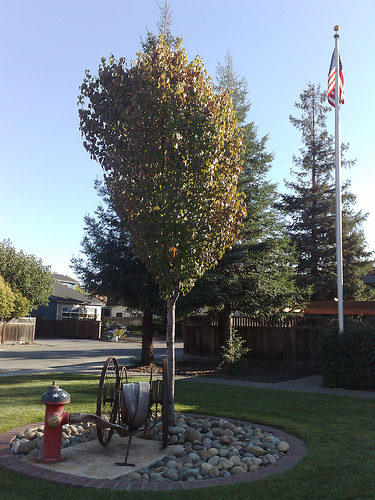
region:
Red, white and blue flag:
[322, 40, 349, 113]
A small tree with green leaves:
[78, 31, 249, 453]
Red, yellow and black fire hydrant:
[37, 377, 74, 464]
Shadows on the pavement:
[0, 340, 185, 378]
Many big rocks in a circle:
[1, 403, 308, 495]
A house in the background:
[31, 271, 103, 338]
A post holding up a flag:
[326, 85, 352, 333]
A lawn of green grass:
[2, 367, 370, 495]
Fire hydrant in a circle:
[4, 378, 304, 491]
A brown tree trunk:
[134, 314, 159, 364]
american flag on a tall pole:
[326, 21, 345, 338]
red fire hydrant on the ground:
[35, 379, 70, 463]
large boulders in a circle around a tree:
[0, 399, 308, 490]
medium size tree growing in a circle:
[78, 51, 249, 437]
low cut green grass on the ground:
[0, 372, 372, 496]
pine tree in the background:
[277, 84, 370, 297]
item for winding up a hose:
[93, 354, 170, 470]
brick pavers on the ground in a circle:
[82, 469, 259, 492]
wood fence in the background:
[181, 311, 326, 363]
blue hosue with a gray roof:
[34, 270, 105, 318]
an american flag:
[324, 43, 346, 107]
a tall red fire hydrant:
[38, 380, 71, 463]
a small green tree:
[219, 328, 251, 373]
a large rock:
[276, 439, 291, 453]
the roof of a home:
[44, 275, 102, 305]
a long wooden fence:
[184, 317, 322, 362]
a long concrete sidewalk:
[135, 367, 369, 399]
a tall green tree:
[67, 76, 304, 364]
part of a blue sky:
[1, 0, 109, 40]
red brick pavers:
[127, 478, 181, 493]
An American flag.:
[326, 49, 346, 110]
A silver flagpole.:
[331, 24, 346, 336]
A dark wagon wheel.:
[92, 359, 120, 449]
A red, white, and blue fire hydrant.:
[41, 382, 81, 464]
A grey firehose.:
[73, 369, 151, 463]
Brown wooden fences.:
[2, 312, 336, 374]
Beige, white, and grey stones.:
[14, 411, 288, 477]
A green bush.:
[315, 322, 373, 394]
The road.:
[3, 337, 198, 376]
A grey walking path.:
[96, 366, 372, 414]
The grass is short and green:
[194, 383, 372, 468]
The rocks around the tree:
[184, 422, 264, 477]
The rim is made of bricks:
[112, 449, 303, 499]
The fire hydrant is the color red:
[33, 376, 73, 464]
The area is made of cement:
[60, 428, 182, 487]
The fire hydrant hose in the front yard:
[77, 353, 162, 453]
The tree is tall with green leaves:
[81, 41, 264, 449]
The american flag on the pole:
[314, 14, 356, 120]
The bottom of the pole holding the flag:
[325, 144, 349, 390]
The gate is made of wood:
[194, 315, 323, 360]